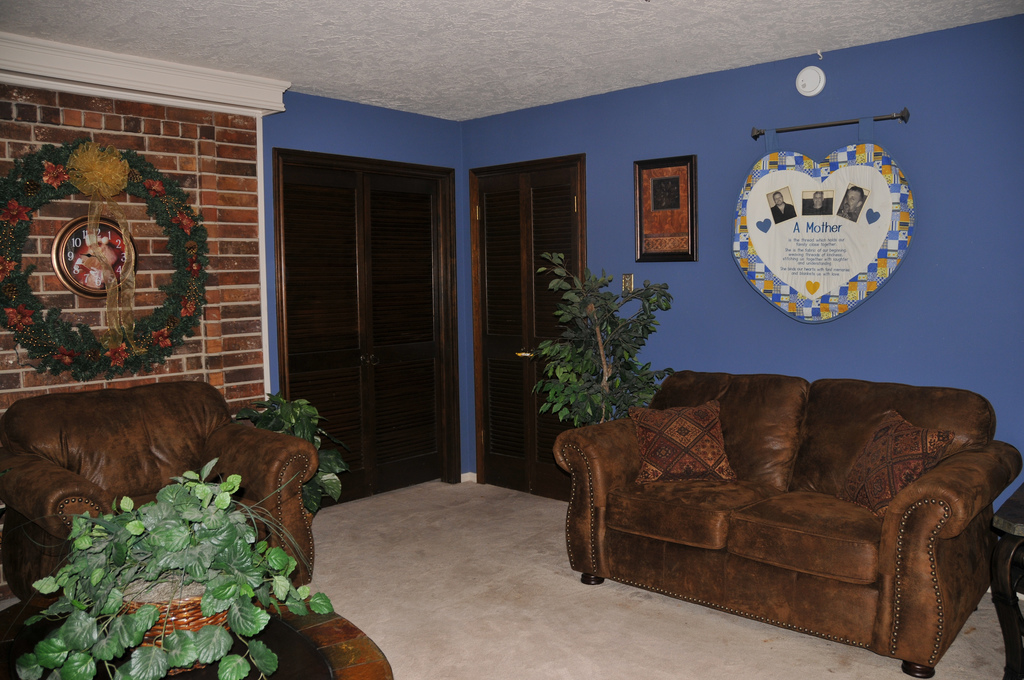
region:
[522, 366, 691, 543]
arm of the couch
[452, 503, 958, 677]
bottom of the couch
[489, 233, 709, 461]
plant next to couch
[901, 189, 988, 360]
blue wall behind couch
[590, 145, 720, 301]
picture on the wall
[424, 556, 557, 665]
rug in front of couch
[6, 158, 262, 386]
bricks on the wall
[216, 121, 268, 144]
a brick in a wall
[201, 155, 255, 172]
a brick in a wall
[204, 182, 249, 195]
a brick in a wall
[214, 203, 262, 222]
a brick in a wall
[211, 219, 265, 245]
a brick in a wall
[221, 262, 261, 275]
a brick in a wall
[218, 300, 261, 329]
a brick in a wall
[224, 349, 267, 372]
a brick in a wall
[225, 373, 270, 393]
a brick in a wall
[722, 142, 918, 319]
A picture on a wall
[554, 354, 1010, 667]
A brown love seat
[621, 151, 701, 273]
A framed picture on a wall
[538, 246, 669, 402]
A plant near a love seat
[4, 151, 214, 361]
A wreath on a wall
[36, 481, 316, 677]
A plant in a basket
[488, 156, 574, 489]
A brown door in a wall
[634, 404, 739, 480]
A pillow on a love seat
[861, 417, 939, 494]
A pillow on a love seat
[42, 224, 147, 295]
A clock on a wall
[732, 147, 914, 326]
the heart hanging on the wall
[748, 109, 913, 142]
the bar hanging on the wall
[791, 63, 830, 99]
the fire alarm on the wall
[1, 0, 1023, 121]
the white ceiling above the couch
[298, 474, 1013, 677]
the white carpet on the ground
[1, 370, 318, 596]
the leather chair against the brick wall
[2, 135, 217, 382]
the green wreathe on the brick wall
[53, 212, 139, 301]
the round clock on the brick wall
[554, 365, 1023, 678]
the brown couch agianst the blue wall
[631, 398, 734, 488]
the square throw pillow on the couch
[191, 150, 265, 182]
brick on the far wall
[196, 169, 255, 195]
brick on the far wall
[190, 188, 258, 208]
brick on the far wall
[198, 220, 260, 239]
brick on the far wall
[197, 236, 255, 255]
brick on the far wall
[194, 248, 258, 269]
brick on the far wall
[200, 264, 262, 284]
brick on the far wall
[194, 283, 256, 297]
brick on the far wall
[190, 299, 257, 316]
brick on the far wall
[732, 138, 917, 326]
A large heart over the couch.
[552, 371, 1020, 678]
Two seat brown couch.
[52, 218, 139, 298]
Brown and black clock with white numbers.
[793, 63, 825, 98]
White round smoke detector.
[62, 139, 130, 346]
A gold bow made of ribbon.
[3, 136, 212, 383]
A large round wreath.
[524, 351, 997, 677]
a brown sofa in room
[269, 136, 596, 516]
two sets of doors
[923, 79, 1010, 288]
the paint is blue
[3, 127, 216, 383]
a large reef on wall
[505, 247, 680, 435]
a green tree in house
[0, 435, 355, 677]
a plant in a basket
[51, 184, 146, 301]
a clock on the wall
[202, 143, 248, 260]
red bricks on the wall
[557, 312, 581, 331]
green leaves on the plant